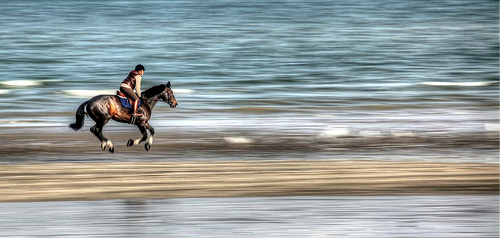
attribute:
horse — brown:
[66, 81, 176, 154]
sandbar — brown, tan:
[0, 164, 499, 203]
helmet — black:
[136, 63, 146, 72]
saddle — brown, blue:
[118, 89, 141, 127]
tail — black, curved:
[68, 100, 88, 130]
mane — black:
[143, 83, 164, 99]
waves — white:
[0, 78, 500, 134]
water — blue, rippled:
[2, 0, 499, 160]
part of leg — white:
[147, 135, 154, 145]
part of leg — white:
[132, 139, 140, 145]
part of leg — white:
[107, 139, 113, 149]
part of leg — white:
[102, 141, 106, 149]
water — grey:
[0, 193, 499, 237]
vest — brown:
[123, 71, 136, 87]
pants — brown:
[122, 87, 138, 99]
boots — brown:
[131, 99, 140, 116]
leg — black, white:
[127, 124, 148, 148]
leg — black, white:
[90, 121, 107, 149]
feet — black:
[127, 138, 134, 148]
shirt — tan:
[118, 73, 143, 94]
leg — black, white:
[145, 122, 155, 143]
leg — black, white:
[97, 125, 108, 144]